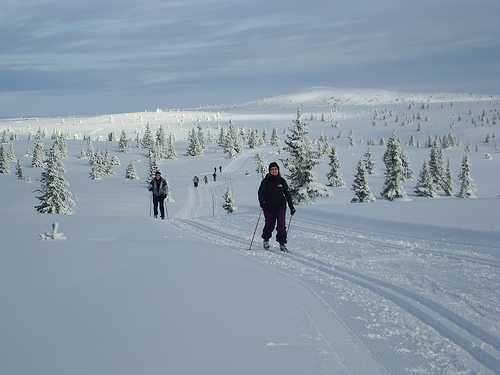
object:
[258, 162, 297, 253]
woman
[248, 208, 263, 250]
ski pole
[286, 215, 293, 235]
ski pole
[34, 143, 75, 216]
tree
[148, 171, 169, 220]
man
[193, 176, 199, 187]
person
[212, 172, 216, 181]
person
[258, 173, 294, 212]
jacket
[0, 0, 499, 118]
sky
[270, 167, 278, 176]
face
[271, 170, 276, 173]
smile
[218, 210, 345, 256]
ski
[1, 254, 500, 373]
snow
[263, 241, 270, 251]
boot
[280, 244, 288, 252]
boot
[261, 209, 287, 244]
pants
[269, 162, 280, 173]
hat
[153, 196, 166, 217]
pants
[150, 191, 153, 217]
ski pole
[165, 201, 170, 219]
ski pole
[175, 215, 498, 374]
ski track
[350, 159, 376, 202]
snow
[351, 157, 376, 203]
tree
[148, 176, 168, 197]
jacket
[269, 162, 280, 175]
head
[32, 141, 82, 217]
snow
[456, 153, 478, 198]
tree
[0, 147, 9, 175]
tree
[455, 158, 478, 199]
snow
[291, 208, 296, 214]
hand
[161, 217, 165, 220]
boot